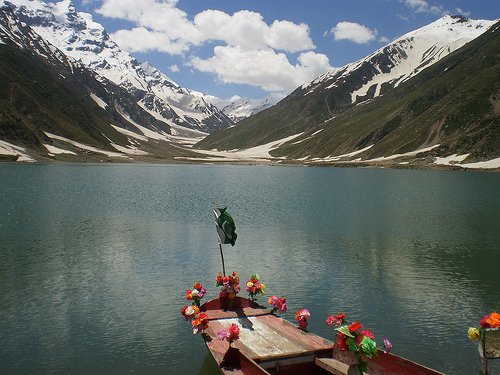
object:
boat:
[198, 296, 447, 375]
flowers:
[215, 271, 241, 312]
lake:
[1, 162, 497, 373]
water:
[0, 161, 499, 374]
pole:
[217, 237, 227, 277]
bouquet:
[186, 281, 206, 308]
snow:
[400, 15, 496, 59]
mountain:
[189, 12, 498, 169]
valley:
[157, 115, 248, 164]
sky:
[37, 1, 499, 100]